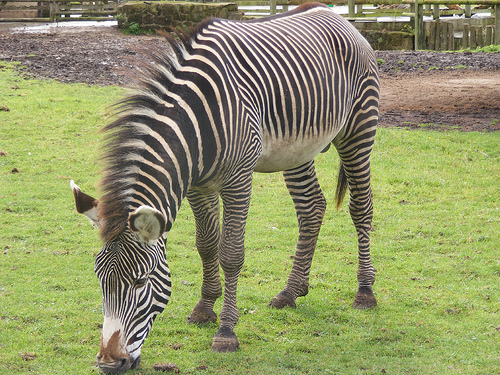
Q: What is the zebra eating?
A: Grass.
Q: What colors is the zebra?
A: Black and white.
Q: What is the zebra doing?
A: Eating.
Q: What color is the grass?
A: Green.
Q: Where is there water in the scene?
A: Background.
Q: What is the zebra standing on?
A: Grass.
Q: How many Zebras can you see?
A: 1.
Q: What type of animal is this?
A: Zebra.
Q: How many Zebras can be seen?
A: One.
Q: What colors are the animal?
A: Black and white.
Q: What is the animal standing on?
A: Green grass.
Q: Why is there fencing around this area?
A: To keep the Zebra in.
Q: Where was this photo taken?
A: A Zoo.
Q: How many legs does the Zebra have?
A: Four.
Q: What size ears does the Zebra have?
A: Large ones.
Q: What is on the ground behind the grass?
A: Muddy dirt.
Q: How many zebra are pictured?
A: One.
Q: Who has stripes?
A: Zebra.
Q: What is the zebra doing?
A: Grazing.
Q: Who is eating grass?
A: The zebra.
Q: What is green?
A: The grass.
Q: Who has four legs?
A: The zebra.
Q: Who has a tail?
A: The zebra.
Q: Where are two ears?
A: On zebra's head.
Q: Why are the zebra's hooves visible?
A: The grass is short.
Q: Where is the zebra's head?
A: Near the ground.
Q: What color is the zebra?
A: The zebra is white and black.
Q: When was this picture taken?
A: This picture was taken in the day time.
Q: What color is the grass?
A: The grass is green.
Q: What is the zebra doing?
A: The zebra is eating grass.